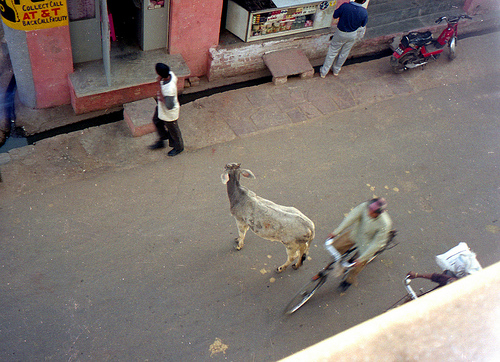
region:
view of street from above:
[0, 2, 497, 359]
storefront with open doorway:
[0, 0, 222, 115]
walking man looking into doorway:
[1, 7, 221, 157]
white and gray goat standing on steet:
[0, 32, 497, 359]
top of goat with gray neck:
[220, 161, 314, 271]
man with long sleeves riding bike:
[285, 195, 397, 314]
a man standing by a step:
[126, 57, 180, 158]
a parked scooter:
[384, 12, 470, 73]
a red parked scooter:
[383, 12, 478, 74]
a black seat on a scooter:
[400, 29, 435, 46]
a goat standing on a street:
[220, 154, 308, 270]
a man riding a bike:
[282, 195, 392, 322]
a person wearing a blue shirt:
[333, 5, 368, 34]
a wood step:
[259, 44, 314, 88]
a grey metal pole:
[94, 2, 114, 84]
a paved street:
[0, 150, 188, 360]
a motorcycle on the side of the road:
[385, 10, 475, 78]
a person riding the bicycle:
[280, 191, 402, 321]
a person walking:
[141, 59, 186, 159]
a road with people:
[3, 36, 489, 336]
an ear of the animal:
[217, 167, 233, 187]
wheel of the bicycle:
[277, 271, 329, 321]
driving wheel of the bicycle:
[322, 230, 365, 272]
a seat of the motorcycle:
[401, 27, 436, 47]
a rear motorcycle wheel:
[386, 46, 422, 78]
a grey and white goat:
[216, 159, 321, 277]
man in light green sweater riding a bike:
[285, 192, 400, 317]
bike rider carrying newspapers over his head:
[401, 229, 486, 307]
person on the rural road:
[150, 60, 185, 160]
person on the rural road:
[326, 197, 388, 293]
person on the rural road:
[317, 0, 369, 79]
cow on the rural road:
[220, 159, 316, 276]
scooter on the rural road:
[388, 10, 474, 76]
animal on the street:
[183, 131, 343, 283]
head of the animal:
[206, 148, 262, 203]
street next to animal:
[79, 185, 199, 287]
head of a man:
[353, 175, 402, 229]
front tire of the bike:
[262, 255, 351, 324]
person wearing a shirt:
[328, 182, 413, 269]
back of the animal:
[263, 194, 339, 273]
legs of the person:
[132, 107, 206, 171]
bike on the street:
[378, 10, 478, 82]